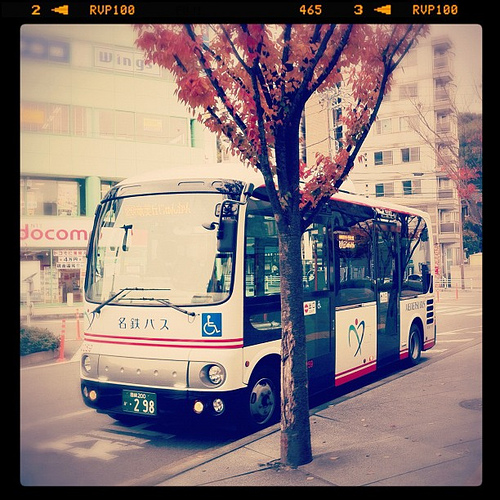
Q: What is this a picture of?
A: Bus.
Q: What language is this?
A: Chinese.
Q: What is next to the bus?
A: Tree.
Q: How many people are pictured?
A: 0.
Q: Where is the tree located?
A: Sidewalk.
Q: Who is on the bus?
A: Driver.